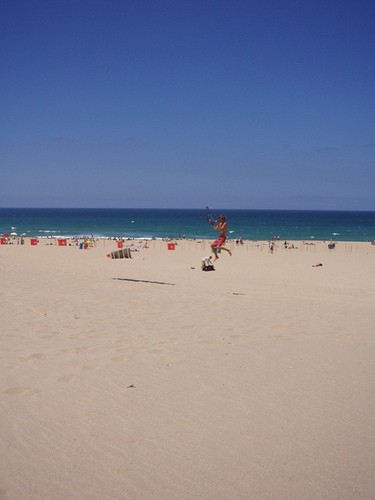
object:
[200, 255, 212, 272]
man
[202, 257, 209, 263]
white shirt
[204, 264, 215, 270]
something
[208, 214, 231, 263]
boy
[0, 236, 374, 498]
beach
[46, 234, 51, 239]
chair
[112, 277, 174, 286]
shadow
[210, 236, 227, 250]
shorts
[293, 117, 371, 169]
white clouds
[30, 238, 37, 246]
red barrels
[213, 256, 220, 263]
bare feet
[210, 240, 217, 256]
legs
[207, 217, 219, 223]
rod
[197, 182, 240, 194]
white clouds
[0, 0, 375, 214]
blue sky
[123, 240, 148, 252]
chair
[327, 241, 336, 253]
chair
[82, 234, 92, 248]
chair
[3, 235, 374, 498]
sand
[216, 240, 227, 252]
legs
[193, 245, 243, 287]
sand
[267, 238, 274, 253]
person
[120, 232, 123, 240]
person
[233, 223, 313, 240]
wave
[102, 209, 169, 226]
waves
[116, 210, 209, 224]
surface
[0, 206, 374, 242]
ocean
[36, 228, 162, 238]
white caps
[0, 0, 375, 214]
clouds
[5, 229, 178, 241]
waves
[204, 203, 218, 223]
handle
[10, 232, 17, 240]
umbrella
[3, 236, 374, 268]
shore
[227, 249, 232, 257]
foot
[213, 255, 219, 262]
foot